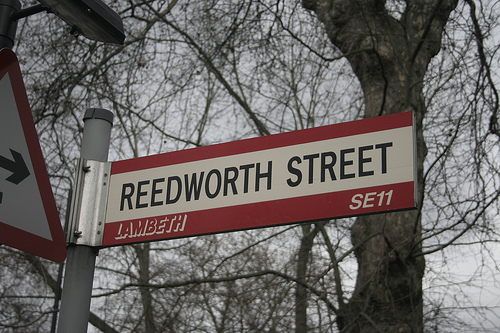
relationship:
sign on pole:
[75, 107, 455, 251] [59, 99, 118, 332]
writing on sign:
[106, 138, 411, 239] [75, 107, 455, 251]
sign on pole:
[0, 41, 80, 266] [59, 99, 118, 332]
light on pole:
[1, 0, 140, 67] [59, 99, 118, 332]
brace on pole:
[62, 156, 115, 250] [59, 99, 118, 332]